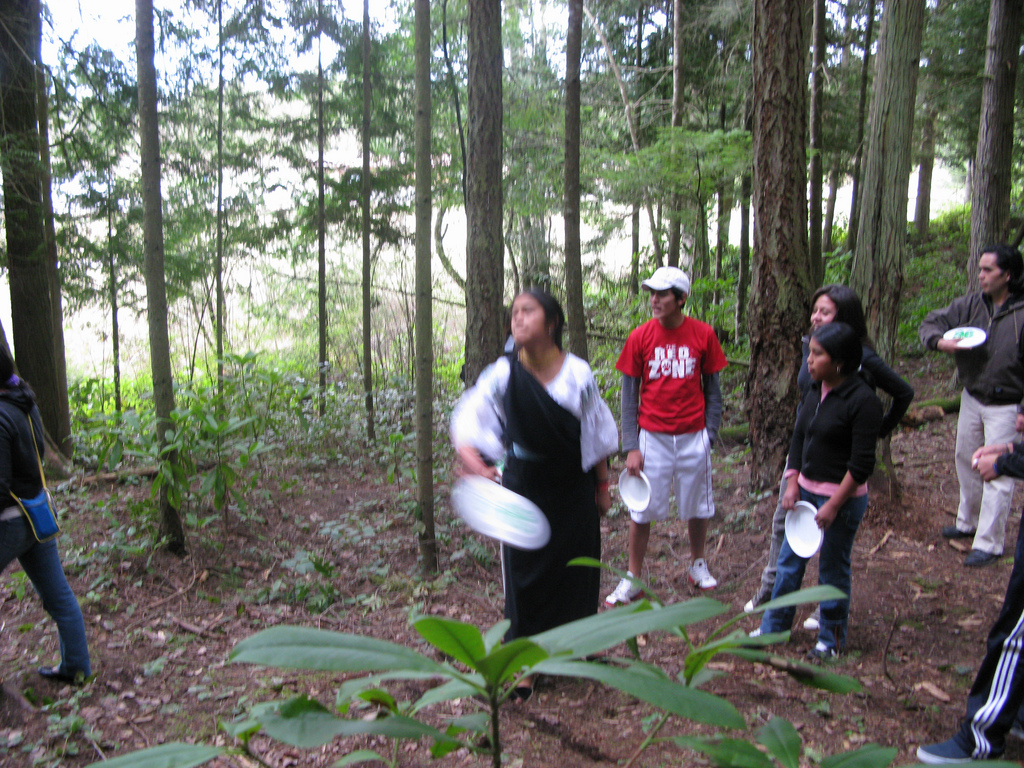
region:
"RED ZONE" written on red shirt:
[611, 307, 733, 444]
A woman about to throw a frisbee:
[427, 272, 633, 567]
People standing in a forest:
[0, 0, 1018, 762]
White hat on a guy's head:
[630, 256, 701, 326]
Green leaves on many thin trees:
[0, 0, 1015, 592]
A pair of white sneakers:
[596, 547, 721, 608]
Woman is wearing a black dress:
[495, 354, 595, 639]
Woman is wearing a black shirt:
[792, 332, 910, 424]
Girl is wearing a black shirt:
[785, 376, 884, 482]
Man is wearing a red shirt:
[615, 316, 721, 437]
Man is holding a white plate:
[615, 461, 654, 518]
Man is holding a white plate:
[943, 322, 985, 354]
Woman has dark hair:
[810, 323, 859, 382]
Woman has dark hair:
[808, 284, 867, 324]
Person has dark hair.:
[506, 294, 573, 361]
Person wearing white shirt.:
[449, 358, 636, 488]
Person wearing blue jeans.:
[6, 500, 123, 700]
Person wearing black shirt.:
[5, 379, 43, 498]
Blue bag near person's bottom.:
[18, 477, 73, 544]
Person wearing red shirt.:
[610, 323, 734, 421]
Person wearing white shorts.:
[616, 427, 749, 546]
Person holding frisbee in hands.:
[768, 481, 839, 581]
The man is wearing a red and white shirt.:
[625, 306, 717, 423]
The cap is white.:
[641, 268, 699, 300]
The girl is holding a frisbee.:
[784, 325, 879, 646]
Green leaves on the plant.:
[240, 614, 526, 726]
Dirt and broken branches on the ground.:
[94, 497, 462, 671]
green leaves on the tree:
[634, 173, 669, 199]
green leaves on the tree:
[365, 82, 400, 163]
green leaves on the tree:
[275, 193, 339, 263]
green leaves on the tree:
[93, 132, 183, 269]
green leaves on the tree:
[87, 202, 116, 316]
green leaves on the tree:
[93, 70, 119, 134]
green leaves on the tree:
[219, 164, 262, 248]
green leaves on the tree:
[228, 127, 312, 205]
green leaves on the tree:
[597, 116, 697, 212]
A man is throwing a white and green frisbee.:
[912, 234, 1023, 573]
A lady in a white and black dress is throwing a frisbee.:
[439, 250, 624, 703]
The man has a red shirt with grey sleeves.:
[604, 252, 735, 610]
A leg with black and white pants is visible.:
[909, 500, 1020, 763]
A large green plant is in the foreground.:
[50, 576, 974, 766]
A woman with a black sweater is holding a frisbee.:
[746, 316, 895, 658]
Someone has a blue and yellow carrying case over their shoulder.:
[0, 300, 99, 705]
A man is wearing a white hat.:
[606, 258, 733, 607]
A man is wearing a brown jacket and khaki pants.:
[912, 227, 1023, 567]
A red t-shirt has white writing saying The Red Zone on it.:
[612, 312, 736, 439]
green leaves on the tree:
[359, 37, 426, 121]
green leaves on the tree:
[669, 271, 701, 300]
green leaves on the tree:
[8, 95, 98, 209]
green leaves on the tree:
[178, 192, 254, 367]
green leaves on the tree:
[131, 247, 259, 334]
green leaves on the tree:
[87, 361, 154, 445]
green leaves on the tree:
[283, 353, 344, 399]